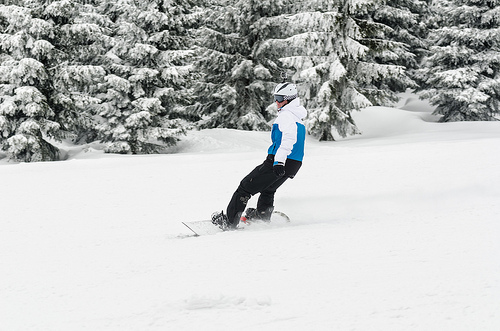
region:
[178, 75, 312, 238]
Person snowboarding on snow.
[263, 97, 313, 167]
Person dressed in blue and white jacket with hood.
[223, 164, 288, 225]
Person dressed in black pants.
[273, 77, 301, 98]
Person wearing white safety helmet.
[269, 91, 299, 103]
Person wearing goggles over eyes.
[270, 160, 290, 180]
Person wearing black glove on hand.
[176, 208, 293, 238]
Snowboard attached to person's feet.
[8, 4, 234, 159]
Snow covered pine trees along ski trail.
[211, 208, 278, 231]
Person dressed in black shoes.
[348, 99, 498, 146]
Snow piled up around pine trees.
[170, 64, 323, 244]
a man riding a snowboard.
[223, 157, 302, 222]
a pair of black pants.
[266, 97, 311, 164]
a blue and white shirt.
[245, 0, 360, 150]
a tree covered in snow.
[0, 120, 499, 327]
a snow covered ground.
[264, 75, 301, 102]
a man wearing a white hat.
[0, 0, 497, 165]
a forest of snow covered trees.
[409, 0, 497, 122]
a tree with snow all over it.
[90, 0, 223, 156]
a tree snow covered tree.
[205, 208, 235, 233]
a left foot shoe.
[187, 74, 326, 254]
person snow boarding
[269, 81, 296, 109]
person wearing goggles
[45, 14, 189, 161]
snowy white pin trees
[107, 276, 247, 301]
fresh white wintry snow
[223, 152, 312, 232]
person wearing black pants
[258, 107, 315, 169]
person wearing blue and white jacket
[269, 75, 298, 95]
the hat the person is wearing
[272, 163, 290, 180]
black mitten the person is wearing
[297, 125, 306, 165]
blue part of the coat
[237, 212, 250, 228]
red on the snow board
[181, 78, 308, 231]
person snow boarding down a slope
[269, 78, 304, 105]
person wearing helmet and goggles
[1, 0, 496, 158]
snow covering pine trees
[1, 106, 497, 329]
snow covering the ground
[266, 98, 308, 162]
skaer is wearing a blue and white ski jacket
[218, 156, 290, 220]
skier is wearing black ski pants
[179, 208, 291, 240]
skate board is tilted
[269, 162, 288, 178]
skier is wearing gloves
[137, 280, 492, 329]
tracks in the white snow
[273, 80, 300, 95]
helmet has black stripe on it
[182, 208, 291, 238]
white snowboard on white snow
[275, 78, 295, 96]
person wearing a white helmet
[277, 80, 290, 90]
black stripe on helmet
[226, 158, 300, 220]
person wearing black snow pants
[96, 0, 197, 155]
snowy pine tree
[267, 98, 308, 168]
person wearing hooded jacket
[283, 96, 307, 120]
white hood on jacket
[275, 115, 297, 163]
white sleeve on jacket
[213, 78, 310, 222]
person is snowboarding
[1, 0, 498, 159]
trees behind person